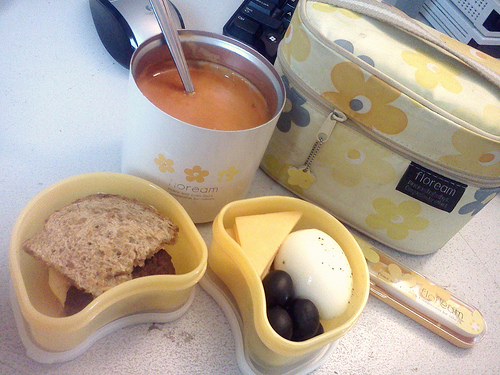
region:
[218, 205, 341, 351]
cheese on a container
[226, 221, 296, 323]
cheese on a container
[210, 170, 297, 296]
cheese on a container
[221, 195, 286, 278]
cheese on a container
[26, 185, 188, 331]
partial sandwich with meat and egg in yellow container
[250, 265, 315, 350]
4-5 black olives in yellow container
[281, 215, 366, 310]
boiled egg with a dash of pepper in yellow container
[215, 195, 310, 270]
sliced cheese in triangle shape in yellow container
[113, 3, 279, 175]
tomato soup with spoon in matching flower thermos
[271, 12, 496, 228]
flowered insulated lunchbox with zipper and handle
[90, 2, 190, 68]
black and silver logitech computer mouse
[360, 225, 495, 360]
flowered plastic utensils by floream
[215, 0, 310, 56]
small portion of keyboard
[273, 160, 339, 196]
flower charm with silver chain attached to zipper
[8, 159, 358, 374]
Food in plastic containers sitting on table.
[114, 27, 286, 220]
Container of tomato soup.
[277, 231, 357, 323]
Boiled egg in plastic container.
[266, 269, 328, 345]
Black olives in plastic container.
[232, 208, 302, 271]
Slices of cheese in plastic container.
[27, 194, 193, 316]
A sandwich in plastic container.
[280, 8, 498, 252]
White plastic lunch bag covered in yellow and orange flowers.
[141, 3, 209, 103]
Handle of spoon inside container of soup.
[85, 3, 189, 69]
Computer mouse lying on table.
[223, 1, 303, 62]
Edge of computer keyboard.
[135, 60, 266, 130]
tomato soup in can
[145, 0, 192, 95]
silver utensil in soup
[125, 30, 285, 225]
round white metal can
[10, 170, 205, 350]
yellow plastic container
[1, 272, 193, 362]
white lid under container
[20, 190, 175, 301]
cut wheat bread in container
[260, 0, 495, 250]
floral print lunch box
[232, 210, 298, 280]
triangle shaped yellow cheese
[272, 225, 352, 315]
white hard boiled egg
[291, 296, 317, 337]
oval dark purple grape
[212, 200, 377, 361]
egg, cheese and olives in yellow container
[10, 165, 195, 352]
sandwich in yellow container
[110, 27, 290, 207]
soup in metal conainer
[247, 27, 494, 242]
flower patterened lunch bag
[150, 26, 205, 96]
spoon in soup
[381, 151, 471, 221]
Floream brand lunch container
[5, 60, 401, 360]
food sitting on desk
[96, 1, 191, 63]
black and silver logitek mouse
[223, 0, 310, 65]
corner of black keyboard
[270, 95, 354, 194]
flower cut out as decorative zipper hanger